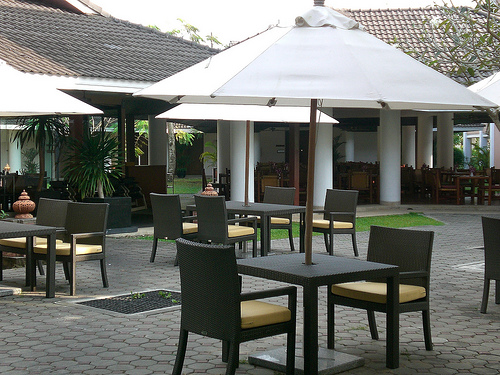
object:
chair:
[298, 178, 364, 258]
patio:
[0, 187, 493, 372]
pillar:
[223, 117, 265, 212]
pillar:
[304, 105, 339, 212]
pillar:
[371, 109, 409, 207]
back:
[363, 219, 443, 290]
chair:
[322, 217, 444, 370]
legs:
[377, 268, 407, 370]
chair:
[165, 226, 304, 374]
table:
[179, 193, 305, 256]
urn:
[7, 184, 45, 227]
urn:
[197, 177, 223, 208]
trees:
[15, 112, 66, 201]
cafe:
[0, 0, 497, 374]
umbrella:
[0, 51, 115, 140]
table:
[221, 237, 403, 375]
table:
[0, 208, 71, 301]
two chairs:
[165, 201, 458, 375]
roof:
[126, 0, 500, 131]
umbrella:
[126, 0, 496, 261]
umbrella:
[144, 87, 338, 260]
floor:
[0, 206, 498, 374]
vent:
[66, 283, 190, 323]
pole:
[300, 98, 323, 269]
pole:
[238, 120, 257, 204]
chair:
[23, 193, 122, 304]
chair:
[28, 197, 122, 298]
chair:
[139, 183, 204, 266]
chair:
[188, 191, 265, 260]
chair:
[241, 174, 302, 255]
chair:
[473, 211, 500, 317]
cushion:
[238, 292, 294, 330]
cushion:
[31, 238, 105, 259]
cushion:
[0, 232, 62, 250]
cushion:
[181, 219, 200, 235]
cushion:
[225, 219, 260, 239]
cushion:
[270, 214, 292, 226]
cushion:
[308, 213, 354, 233]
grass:
[244, 212, 446, 242]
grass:
[164, 174, 208, 199]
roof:
[1, 1, 500, 91]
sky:
[79, 0, 485, 53]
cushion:
[328, 272, 430, 305]